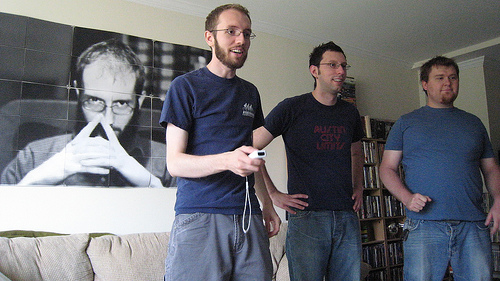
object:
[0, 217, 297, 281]
couch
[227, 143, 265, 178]
hand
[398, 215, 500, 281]
jeans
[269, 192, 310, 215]
hands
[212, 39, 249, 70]
beard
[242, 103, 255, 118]
print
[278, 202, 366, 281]
jeans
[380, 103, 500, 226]
shirt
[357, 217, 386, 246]
shelves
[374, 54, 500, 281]
man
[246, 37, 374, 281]
man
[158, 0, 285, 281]
man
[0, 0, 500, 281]
room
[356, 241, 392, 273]
shelves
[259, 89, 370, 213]
shirt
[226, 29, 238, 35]
man's eyes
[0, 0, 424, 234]
wall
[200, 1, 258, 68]
head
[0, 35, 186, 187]
man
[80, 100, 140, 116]
glasses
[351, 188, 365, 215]
hands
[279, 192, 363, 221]
hips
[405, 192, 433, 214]
fist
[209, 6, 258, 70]
face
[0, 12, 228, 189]
photo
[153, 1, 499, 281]
three men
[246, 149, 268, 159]
control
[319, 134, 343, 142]
red words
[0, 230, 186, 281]
two pillows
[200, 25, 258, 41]
glasses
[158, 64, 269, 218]
shirt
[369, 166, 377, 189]
books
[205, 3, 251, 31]
hair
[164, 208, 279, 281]
blue jeans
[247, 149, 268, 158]
controller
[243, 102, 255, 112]
white writing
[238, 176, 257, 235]
strap